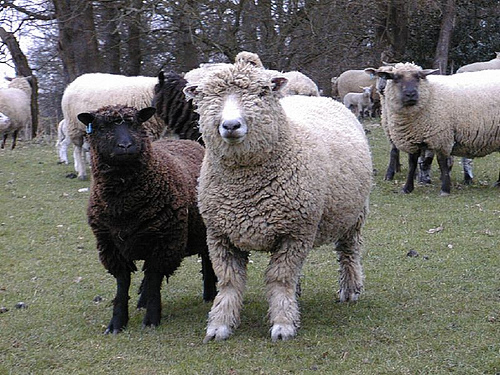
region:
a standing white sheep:
[180, 58, 368, 340]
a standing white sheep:
[366, 57, 493, 189]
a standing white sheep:
[61, 65, 181, 177]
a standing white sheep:
[0, 70, 31, 140]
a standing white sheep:
[325, 66, 380, 103]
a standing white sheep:
[340, 85, 370, 111]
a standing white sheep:
[232, 50, 317, 100]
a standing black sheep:
[75, 105, 216, 331]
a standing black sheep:
[145, 67, 210, 147]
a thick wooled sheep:
[186, 64, 378, 348]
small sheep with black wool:
[61, 97, 237, 333]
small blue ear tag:
[76, 120, 101, 140]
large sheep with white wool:
[176, 51, 386, 348]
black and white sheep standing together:
[49, 52, 383, 344]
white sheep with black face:
[358, 51, 499, 208]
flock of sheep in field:
[2, 0, 499, 366]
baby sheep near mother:
[337, 77, 378, 118]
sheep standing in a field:
[171, 49, 498, 369]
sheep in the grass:
[3, 2, 498, 364]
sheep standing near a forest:
[1, 3, 498, 368]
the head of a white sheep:
[175, 54, 295, 166]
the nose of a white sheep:
[220, 115, 243, 133]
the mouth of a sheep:
[215, 130, 245, 141]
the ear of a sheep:
[262, 65, 292, 95]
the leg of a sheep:
[261, 225, 316, 316]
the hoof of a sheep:
[265, 315, 305, 340]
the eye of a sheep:
[255, 86, 272, 103]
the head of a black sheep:
[69, 95, 166, 176]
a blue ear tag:
[81, 116, 98, 136]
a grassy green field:
[1, 133, 498, 373]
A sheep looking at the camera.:
[177, 57, 374, 342]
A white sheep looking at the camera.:
[183, 51, 373, 343]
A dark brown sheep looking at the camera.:
[74, 103, 217, 334]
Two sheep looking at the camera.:
[74, 49, 374, 345]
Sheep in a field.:
[1, 50, 497, 342]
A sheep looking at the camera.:
[77, 101, 215, 335]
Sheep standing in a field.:
[74, 59, 374, 345]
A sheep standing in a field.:
[362, 59, 497, 196]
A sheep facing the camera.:
[362, 62, 495, 199]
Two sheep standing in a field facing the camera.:
[74, 57, 374, 344]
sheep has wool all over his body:
[200, 75, 407, 309]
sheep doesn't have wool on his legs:
[387, 66, 497, 185]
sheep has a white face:
[216, 102, 266, 153]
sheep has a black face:
[393, 68, 421, 110]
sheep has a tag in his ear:
[61, 110, 96, 155]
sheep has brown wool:
[82, 102, 220, 300]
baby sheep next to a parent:
[338, 77, 383, 129]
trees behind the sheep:
[49, 3, 487, 95]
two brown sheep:
[50, 82, 275, 323]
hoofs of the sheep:
[198, 321, 312, 341]